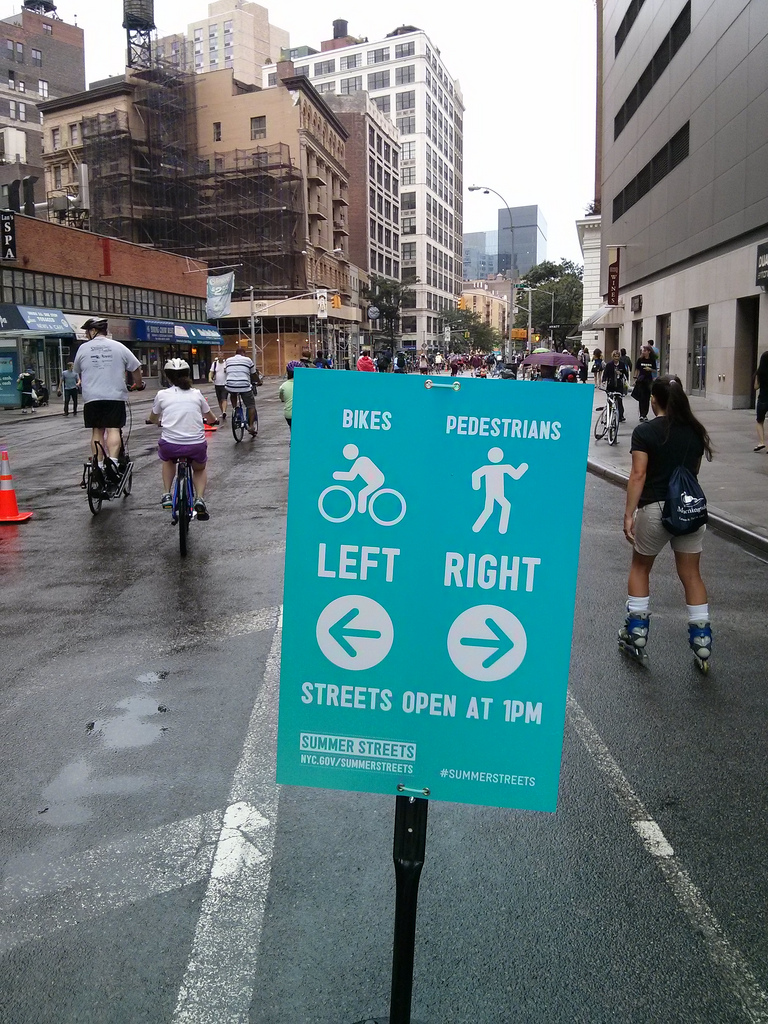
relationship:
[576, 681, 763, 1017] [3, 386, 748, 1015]
line on street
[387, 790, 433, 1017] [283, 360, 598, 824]
pole under sign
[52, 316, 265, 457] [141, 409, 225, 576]
people riding bicycle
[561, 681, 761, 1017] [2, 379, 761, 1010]
line on ground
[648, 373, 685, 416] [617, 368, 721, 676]
head of girl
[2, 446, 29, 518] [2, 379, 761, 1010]
cone of ground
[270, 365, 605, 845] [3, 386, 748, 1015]
sign in street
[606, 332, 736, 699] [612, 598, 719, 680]
girl wearing rollerblades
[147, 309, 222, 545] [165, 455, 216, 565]
girl riding a bike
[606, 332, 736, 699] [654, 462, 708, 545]
girl carrying a bag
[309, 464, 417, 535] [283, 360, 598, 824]
bicycle on sign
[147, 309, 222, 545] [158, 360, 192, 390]
girl wearing helmet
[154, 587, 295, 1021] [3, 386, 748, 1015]
line on street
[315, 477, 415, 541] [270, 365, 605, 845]
bicycle on sign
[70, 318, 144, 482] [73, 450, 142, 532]
man riding a cycle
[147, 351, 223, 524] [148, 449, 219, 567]
girl riding a bicycle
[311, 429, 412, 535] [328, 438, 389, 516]
being depicting being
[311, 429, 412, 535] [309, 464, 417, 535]
being depicting bicycle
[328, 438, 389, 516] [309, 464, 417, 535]
being riding bicycle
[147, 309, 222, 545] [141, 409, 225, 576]
girl riding bicycle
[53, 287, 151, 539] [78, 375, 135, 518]
man riding bike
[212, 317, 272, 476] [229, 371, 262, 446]
people riding bike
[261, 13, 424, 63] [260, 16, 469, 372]
top belonging to building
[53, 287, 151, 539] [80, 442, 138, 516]
man riding bike